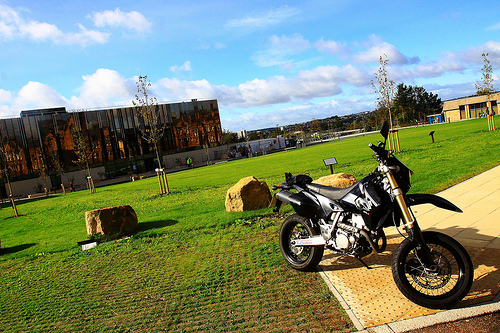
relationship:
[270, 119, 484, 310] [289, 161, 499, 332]
motorcycle on sidewalk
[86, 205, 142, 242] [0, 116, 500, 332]
rock in grass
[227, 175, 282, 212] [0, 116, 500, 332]
left rock in grass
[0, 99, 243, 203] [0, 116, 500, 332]
building behind grass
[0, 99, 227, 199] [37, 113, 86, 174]
building in window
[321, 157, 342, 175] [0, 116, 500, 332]
display in grass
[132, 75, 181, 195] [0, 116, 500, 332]
thin tree in grass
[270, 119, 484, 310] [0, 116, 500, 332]
bike beside grass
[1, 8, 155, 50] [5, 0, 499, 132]
clouds in sky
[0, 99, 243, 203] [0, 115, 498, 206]
building on sidewalk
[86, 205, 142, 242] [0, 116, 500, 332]
rock on grass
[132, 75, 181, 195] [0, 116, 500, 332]
tree sapling in grass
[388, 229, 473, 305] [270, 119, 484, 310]
tire in front of dirt bike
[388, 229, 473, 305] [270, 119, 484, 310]
tire of dirt bike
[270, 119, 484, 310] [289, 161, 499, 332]
black dirtbike parked on pavement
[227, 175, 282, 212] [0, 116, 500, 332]
large rocks in grass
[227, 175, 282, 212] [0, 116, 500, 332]
large rock in grass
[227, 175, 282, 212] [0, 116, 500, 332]
large rock on grass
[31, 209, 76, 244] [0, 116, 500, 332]
patch of green grass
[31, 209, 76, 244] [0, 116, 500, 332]
patch of grass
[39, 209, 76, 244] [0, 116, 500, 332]
patch of some grass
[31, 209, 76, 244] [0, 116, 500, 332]
patch of some green grass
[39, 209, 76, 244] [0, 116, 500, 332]
patch of grass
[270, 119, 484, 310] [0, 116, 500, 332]
motorcycle parked in field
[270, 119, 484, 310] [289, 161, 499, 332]
motorcycle parked by pavement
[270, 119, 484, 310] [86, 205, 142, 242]
motorcycle by rock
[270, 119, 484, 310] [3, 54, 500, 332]
motorcycle parked in city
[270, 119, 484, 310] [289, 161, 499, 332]
new motorcycle on pavement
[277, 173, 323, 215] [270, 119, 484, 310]
motor on motorcycle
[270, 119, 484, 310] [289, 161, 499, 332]
motorcycle on street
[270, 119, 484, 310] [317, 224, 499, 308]
motorcycle casting shadow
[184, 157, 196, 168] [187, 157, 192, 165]
person wearing green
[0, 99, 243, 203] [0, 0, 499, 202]
building in background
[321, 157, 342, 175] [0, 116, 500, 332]
small sign in grass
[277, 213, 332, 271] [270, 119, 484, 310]
wheel on motorcycle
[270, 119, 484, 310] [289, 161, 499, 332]
black motorcycle on ramp